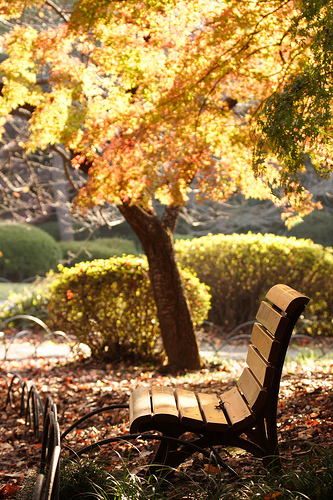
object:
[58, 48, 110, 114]
leaves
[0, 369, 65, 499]
fence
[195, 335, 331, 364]
walkway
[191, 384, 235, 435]
wood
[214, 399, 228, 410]
object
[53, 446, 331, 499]
grass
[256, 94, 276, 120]
ground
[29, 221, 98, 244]
shrub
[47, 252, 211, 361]
bush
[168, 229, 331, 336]
bush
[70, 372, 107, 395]
leaves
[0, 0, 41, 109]
leaves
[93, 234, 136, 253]
bush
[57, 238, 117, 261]
bush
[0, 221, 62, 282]
bush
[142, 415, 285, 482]
base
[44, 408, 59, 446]
black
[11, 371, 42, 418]
gate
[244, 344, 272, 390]
slat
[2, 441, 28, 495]
leaves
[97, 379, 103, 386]
orange leaves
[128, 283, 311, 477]
bench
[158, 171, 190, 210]
leaves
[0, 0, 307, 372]
tree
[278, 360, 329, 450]
dry leaves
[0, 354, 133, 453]
dry leaves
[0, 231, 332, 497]
ground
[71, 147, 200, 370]
tree trunk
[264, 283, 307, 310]
slat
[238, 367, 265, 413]
slat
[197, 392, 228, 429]
slat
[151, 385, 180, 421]
slat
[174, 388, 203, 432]
slat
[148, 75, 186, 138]
leaves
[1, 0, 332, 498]
park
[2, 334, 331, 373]
pathway